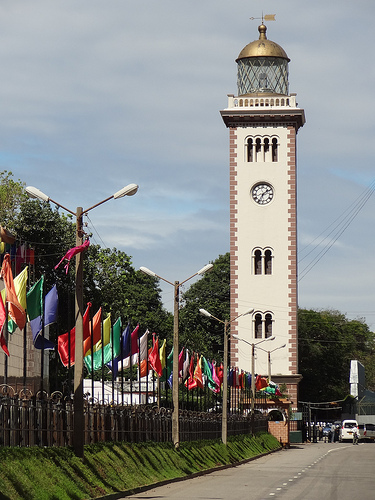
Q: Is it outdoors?
A: Yes, it is outdoors.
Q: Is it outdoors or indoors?
A: It is outdoors.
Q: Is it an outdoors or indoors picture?
A: It is outdoors.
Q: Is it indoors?
A: No, it is outdoors.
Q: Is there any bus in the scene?
A: No, there are no buses.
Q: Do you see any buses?
A: No, there are no buses.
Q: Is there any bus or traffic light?
A: No, there are no buses or traffic lights.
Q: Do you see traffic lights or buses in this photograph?
A: No, there are no buses or traffic lights.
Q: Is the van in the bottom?
A: Yes, the van is in the bottom of the image.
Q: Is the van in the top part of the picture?
A: No, the van is in the bottom of the image.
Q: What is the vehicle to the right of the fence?
A: The vehicle is a van.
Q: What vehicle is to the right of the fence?
A: The vehicle is a van.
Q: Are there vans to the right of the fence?
A: Yes, there is a van to the right of the fence.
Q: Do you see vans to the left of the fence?
A: No, the van is to the right of the fence.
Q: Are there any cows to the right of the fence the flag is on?
A: No, there is a van to the right of the fence.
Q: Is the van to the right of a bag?
A: No, the van is to the right of a fence.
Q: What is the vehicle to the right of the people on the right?
A: The vehicle is a van.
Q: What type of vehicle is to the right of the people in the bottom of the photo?
A: The vehicle is a van.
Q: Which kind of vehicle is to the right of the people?
A: The vehicle is a van.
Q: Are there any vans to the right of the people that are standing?
A: Yes, there is a van to the right of the people.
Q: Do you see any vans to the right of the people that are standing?
A: Yes, there is a van to the right of the people.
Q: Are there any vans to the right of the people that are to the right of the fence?
A: Yes, there is a van to the right of the people.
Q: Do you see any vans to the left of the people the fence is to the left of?
A: No, the van is to the right of the people.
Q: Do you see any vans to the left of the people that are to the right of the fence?
A: No, the van is to the right of the people.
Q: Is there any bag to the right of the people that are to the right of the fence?
A: No, there is a van to the right of the people.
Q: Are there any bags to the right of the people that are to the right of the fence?
A: No, there is a van to the right of the people.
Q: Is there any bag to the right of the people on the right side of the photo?
A: No, there is a van to the right of the people.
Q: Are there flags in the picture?
A: Yes, there is a flag.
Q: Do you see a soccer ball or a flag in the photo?
A: Yes, there is a flag.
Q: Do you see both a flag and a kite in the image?
A: No, there is a flag but no kites.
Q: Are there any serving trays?
A: No, there are no serving trays.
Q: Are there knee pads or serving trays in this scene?
A: No, there are no serving trays or knee pads.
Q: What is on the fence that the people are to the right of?
A: The flag is on the fence.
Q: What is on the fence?
A: The flag is on the fence.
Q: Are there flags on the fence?
A: Yes, there is a flag on the fence.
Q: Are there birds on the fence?
A: No, there is a flag on the fence.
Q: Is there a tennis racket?
A: No, there are no rackets.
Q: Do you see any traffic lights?
A: No, there are no traffic lights.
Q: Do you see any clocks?
A: Yes, there is a clock.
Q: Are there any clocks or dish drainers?
A: Yes, there is a clock.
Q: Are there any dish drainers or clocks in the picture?
A: Yes, there is a clock.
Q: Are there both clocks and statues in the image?
A: No, there is a clock but no statues.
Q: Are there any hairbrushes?
A: No, there are no hairbrushes.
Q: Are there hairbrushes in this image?
A: No, there are no hairbrushes.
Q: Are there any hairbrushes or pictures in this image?
A: No, there are no hairbrushes or pictures.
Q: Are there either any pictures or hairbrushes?
A: No, there are no hairbrushes or pictures.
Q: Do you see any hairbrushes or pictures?
A: No, there are no hairbrushes or pictures.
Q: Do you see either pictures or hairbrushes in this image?
A: No, there are no hairbrushes or pictures.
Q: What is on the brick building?
A: The clock is on the building.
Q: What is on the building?
A: The clock is on the building.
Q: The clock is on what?
A: The clock is on the building.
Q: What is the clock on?
A: The clock is on the building.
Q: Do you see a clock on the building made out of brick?
A: Yes, there is a clock on the building.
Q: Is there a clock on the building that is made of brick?
A: Yes, there is a clock on the building.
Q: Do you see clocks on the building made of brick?
A: Yes, there is a clock on the building.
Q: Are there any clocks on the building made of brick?
A: Yes, there is a clock on the building.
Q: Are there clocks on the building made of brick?
A: Yes, there is a clock on the building.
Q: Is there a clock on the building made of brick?
A: Yes, there is a clock on the building.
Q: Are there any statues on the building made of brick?
A: No, there is a clock on the building.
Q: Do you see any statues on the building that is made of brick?
A: No, there is a clock on the building.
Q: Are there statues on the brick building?
A: No, there is a clock on the building.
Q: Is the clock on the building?
A: Yes, the clock is on the building.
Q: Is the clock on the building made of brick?
A: Yes, the clock is on the building.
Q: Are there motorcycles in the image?
A: No, there are no motorcycles.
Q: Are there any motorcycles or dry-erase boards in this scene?
A: No, there are no motorcycles or dry-erase boards.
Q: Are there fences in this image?
A: Yes, there is a fence.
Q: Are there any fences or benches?
A: Yes, there is a fence.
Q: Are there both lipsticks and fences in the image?
A: No, there is a fence but no lipsticks.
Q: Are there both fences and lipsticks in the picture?
A: No, there is a fence but no lipsticks.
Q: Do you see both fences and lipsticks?
A: No, there is a fence but no lipsticks.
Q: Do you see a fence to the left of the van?
A: Yes, there is a fence to the left of the van.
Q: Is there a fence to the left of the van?
A: Yes, there is a fence to the left of the van.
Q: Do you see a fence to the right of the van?
A: No, the fence is to the left of the van.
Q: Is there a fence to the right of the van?
A: No, the fence is to the left of the van.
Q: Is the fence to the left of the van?
A: Yes, the fence is to the left of the van.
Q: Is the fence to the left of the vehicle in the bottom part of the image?
A: Yes, the fence is to the left of the van.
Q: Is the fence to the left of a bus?
A: No, the fence is to the left of the van.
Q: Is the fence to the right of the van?
A: No, the fence is to the left of the van.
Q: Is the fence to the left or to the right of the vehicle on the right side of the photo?
A: The fence is to the left of the van.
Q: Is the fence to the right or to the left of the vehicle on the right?
A: The fence is to the left of the van.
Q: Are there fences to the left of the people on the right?
A: Yes, there is a fence to the left of the people.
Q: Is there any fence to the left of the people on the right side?
A: Yes, there is a fence to the left of the people.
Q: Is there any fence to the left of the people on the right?
A: Yes, there is a fence to the left of the people.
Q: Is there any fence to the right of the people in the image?
A: No, the fence is to the left of the people.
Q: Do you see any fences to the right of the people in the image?
A: No, the fence is to the left of the people.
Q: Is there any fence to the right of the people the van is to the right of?
A: No, the fence is to the left of the people.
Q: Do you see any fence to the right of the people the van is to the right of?
A: No, the fence is to the left of the people.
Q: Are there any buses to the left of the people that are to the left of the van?
A: No, there is a fence to the left of the people.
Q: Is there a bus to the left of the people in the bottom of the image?
A: No, there is a fence to the left of the people.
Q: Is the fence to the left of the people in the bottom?
A: Yes, the fence is to the left of the people.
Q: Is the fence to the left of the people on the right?
A: Yes, the fence is to the left of the people.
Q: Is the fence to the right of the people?
A: No, the fence is to the left of the people.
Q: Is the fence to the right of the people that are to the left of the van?
A: No, the fence is to the left of the people.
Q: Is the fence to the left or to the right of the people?
A: The fence is to the left of the people.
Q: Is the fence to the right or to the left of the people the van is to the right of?
A: The fence is to the left of the people.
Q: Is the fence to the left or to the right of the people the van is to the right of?
A: The fence is to the left of the people.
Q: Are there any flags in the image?
A: Yes, there is a flag.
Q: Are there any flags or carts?
A: Yes, there is a flag.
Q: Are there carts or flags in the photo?
A: Yes, there is a flag.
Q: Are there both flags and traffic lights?
A: No, there is a flag but no traffic lights.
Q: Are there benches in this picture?
A: No, there are no benches.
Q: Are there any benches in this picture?
A: No, there are no benches.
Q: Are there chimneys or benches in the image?
A: No, there are no benches or chimneys.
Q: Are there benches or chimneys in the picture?
A: No, there are no benches or chimneys.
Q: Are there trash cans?
A: No, there are no trash cans.